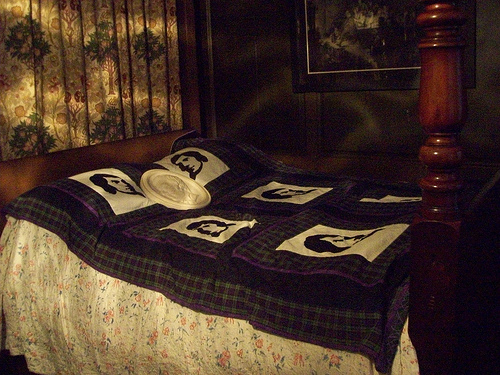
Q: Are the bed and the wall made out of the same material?
A: Yes, both the bed and the wall are made of wood.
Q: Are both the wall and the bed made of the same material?
A: Yes, both the wall and the bed are made of wood.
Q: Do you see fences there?
A: No, there are no fences.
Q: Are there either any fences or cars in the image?
A: No, there are no fences or cars.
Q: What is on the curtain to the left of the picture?
A: The tree is on the curtain.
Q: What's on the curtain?
A: The tree is on the curtain.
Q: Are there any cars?
A: No, there are no cars.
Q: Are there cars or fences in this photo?
A: No, there are no cars or fences.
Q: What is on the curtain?
A: The tree is on the curtain.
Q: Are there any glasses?
A: No, there are no glasses.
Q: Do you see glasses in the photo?
A: No, there are no glasses.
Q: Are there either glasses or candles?
A: No, there are no glasses or candles.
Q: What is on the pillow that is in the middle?
A: The picture is on the pillow.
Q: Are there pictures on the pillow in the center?
A: Yes, there is a picture on the pillow.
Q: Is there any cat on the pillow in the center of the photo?
A: No, there is a picture on the pillow.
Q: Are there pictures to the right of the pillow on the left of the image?
A: Yes, there is a picture to the right of the pillow.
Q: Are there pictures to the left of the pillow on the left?
A: No, the picture is to the right of the pillow.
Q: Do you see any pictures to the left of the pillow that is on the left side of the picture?
A: No, the picture is to the right of the pillow.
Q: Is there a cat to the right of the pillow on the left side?
A: No, there is a picture to the right of the pillow.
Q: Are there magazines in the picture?
A: No, there are no magazines.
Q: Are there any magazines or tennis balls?
A: No, there are no magazines or tennis balls.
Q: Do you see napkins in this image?
A: No, there are no napkins.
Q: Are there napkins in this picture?
A: No, there are no napkins.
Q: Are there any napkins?
A: No, there are no napkins.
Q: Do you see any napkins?
A: No, there are no napkins.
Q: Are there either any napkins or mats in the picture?
A: No, there are no napkins or mats.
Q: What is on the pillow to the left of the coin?
A: The picture is on the pillow.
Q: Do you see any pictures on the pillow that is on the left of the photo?
A: Yes, there is a picture on the pillow.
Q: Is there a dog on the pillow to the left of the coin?
A: No, there is a picture on the pillow.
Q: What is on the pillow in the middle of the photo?
A: The picture is on the pillow.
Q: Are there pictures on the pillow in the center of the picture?
A: Yes, there is a picture on the pillow.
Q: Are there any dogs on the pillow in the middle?
A: No, there is a picture on the pillow.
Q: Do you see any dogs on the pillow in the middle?
A: No, there is a picture on the pillow.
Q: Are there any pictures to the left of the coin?
A: Yes, there is a picture to the left of the coin.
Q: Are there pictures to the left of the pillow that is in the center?
A: Yes, there is a picture to the left of the pillow.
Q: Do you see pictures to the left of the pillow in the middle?
A: Yes, there is a picture to the left of the pillow.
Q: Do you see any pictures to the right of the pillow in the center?
A: No, the picture is to the left of the pillow.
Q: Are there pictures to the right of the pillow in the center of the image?
A: No, the picture is to the left of the pillow.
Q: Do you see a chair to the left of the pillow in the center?
A: No, there is a picture to the left of the pillow.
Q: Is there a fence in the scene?
A: No, there are no fences.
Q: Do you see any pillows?
A: Yes, there is a pillow.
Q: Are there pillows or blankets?
A: Yes, there is a pillow.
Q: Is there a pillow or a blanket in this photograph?
A: Yes, there is a pillow.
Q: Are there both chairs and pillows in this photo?
A: No, there is a pillow but no chairs.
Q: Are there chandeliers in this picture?
A: No, there are no chandeliers.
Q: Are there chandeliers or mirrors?
A: No, there are no chandeliers or mirrors.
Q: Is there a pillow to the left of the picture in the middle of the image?
A: Yes, there is a pillow to the left of the picture.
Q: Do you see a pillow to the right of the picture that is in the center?
A: No, the pillow is to the left of the picture.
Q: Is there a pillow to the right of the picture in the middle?
A: No, the pillow is to the left of the picture.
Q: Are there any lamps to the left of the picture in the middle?
A: No, there is a pillow to the left of the picture.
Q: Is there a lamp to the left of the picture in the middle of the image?
A: No, there is a pillow to the left of the picture.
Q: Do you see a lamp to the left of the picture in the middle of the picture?
A: No, there is a pillow to the left of the picture.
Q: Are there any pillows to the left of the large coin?
A: Yes, there is a pillow to the left of the coin.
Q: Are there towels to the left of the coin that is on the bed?
A: No, there is a pillow to the left of the coin.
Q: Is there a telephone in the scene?
A: No, there are no phones.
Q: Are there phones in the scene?
A: No, there are no phones.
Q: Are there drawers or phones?
A: No, there are no phones or drawers.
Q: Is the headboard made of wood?
A: Yes, the headboard is made of wood.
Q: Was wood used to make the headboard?
A: Yes, the headboard is made of wood.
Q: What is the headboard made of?
A: The head board is made of wood.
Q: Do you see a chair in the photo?
A: No, there are no chairs.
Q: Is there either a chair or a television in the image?
A: No, there are no chairs or televisions.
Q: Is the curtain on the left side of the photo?
A: Yes, the curtain is on the left of the image.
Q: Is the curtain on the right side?
A: No, the curtain is on the left of the image.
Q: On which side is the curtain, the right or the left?
A: The curtain is on the left of the image.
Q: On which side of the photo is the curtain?
A: The curtain is on the left of the image.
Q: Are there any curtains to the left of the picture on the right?
A: Yes, there is a curtain to the left of the picture.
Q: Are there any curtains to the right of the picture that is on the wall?
A: No, the curtain is to the left of the picture.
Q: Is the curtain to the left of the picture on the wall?
A: Yes, the curtain is to the left of the picture.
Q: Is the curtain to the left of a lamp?
A: No, the curtain is to the left of the picture.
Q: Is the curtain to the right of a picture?
A: No, the curtain is to the left of a picture.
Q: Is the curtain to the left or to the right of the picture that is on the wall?
A: The curtain is to the left of the picture.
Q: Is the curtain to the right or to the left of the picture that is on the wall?
A: The curtain is to the left of the picture.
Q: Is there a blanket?
A: Yes, there is a blanket.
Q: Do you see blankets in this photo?
A: Yes, there is a blanket.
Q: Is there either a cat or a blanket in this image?
A: Yes, there is a blanket.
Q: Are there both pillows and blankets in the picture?
A: Yes, there are both a blanket and a pillow.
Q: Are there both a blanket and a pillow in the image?
A: Yes, there are both a blanket and a pillow.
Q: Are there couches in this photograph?
A: No, there are no couches.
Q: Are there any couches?
A: No, there are no couches.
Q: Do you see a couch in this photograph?
A: No, there are no couches.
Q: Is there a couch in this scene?
A: No, there are no couches.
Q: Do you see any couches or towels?
A: No, there are no couches or towels.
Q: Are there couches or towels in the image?
A: No, there are no couches or towels.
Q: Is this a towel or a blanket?
A: This is a blanket.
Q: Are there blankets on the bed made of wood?
A: Yes, there is a blanket on the bed.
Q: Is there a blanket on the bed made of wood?
A: Yes, there is a blanket on the bed.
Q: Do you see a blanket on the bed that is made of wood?
A: Yes, there is a blanket on the bed.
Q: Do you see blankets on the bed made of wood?
A: Yes, there is a blanket on the bed.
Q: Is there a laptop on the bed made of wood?
A: No, there is a blanket on the bed.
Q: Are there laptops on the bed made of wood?
A: No, there is a blanket on the bed.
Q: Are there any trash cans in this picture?
A: No, there are no trash cans.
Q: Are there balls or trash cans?
A: No, there are no trash cans or balls.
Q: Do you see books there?
A: No, there are no books.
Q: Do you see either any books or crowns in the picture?
A: No, there are no books or crowns.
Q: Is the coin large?
A: Yes, the coin is large.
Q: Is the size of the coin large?
A: Yes, the coin is large.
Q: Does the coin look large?
A: Yes, the coin is large.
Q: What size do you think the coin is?
A: The coin is large.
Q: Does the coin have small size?
A: No, the coin is large.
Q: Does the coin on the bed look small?
A: No, the coin is large.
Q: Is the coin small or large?
A: The coin is large.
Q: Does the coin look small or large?
A: The coin is large.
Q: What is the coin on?
A: The coin is on the bed.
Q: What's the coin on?
A: The coin is on the bed.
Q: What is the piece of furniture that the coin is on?
A: The piece of furniture is a bed.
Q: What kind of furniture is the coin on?
A: The coin is on the bed.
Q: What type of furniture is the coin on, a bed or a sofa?
A: The coin is on a bed.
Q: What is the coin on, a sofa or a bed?
A: The coin is on a bed.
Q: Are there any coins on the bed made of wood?
A: Yes, there is a coin on the bed.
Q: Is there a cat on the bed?
A: No, there is a coin on the bed.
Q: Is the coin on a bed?
A: Yes, the coin is on a bed.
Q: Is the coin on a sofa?
A: No, the coin is on a bed.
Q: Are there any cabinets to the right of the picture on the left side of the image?
A: No, there is a coin to the right of the picture.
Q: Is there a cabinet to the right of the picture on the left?
A: No, there is a coin to the right of the picture.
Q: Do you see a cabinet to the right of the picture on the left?
A: No, there is a coin to the right of the picture.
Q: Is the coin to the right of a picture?
A: Yes, the coin is to the right of a picture.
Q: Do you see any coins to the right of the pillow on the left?
A: Yes, there is a coin to the right of the pillow.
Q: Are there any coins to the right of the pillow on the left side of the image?
A: Yes, there is a coin to the right of the pillow.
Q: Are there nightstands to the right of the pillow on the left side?
A: No, there is a coin to the right of the pillow.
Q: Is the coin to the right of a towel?
A: No, the coin is to the right of a pillow.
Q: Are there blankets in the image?
A: Yes, there is a blanket.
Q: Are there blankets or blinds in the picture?
A: Yes, there is a blanket.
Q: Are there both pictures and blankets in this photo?
A: Yes, there are both a blanket and a picture.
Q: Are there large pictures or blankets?
A: Yes, there is a large blanket.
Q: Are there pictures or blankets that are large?
A: Yes, the blanket is large.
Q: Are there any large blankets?
A: Yes, there is a large blanket.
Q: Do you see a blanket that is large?
A: Yes, there is a blanket that is large.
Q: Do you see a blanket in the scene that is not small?
A: Yes, there is a large blanket.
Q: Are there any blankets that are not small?
A: Yes, there is a large blanket.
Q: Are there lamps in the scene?
A: No, there are no lamps.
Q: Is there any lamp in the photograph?
A: No, there are no lamps.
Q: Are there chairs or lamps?
A: No, there are no lamps or chairs.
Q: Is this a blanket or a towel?
A: This is a blanket.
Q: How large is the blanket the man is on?
A: The blanket is large.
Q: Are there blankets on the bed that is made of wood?
A: Yes, there is a blanket on the bed.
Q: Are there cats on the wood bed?
A: No, there is a blanket on the bed.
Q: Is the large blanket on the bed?
A: Yes, the blanket is on the bed.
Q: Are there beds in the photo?
A: Yes, there is a bed.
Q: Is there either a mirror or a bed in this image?
A: Yes, there is a bed.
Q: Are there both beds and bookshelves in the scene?
A: No, there is a bed but no bookshelves.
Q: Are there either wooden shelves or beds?
A: Yes, there is a wood bed.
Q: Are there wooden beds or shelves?
A: Yes, there is a wood bed.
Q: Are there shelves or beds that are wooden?
A: Yes, the bed is wooden.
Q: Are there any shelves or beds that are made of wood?
A: Yes, the bed is made of wood.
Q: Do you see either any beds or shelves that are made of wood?
A: Yes, the bed is made of wood.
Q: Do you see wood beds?
A: Yes, there is a bed that is made of wood.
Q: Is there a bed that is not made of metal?
A: Yes, there is a bed that is made of wood.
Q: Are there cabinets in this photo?
A: No, there are no cabinets.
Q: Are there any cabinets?
A: No, there are no cabinets.